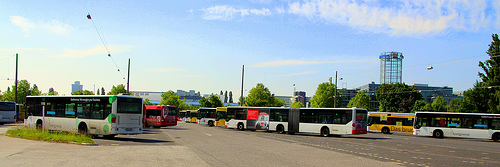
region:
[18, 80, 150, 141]
bus on a road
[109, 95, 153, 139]
the back of a bus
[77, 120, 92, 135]
wheels of a bus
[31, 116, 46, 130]
wheels of a bus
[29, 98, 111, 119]
windows of a bus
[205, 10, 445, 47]
sky full of clouds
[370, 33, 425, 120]
a very tall building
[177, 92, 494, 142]
many buses parked on road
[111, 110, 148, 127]
tail lights of a bus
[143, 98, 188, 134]
a red bus parked on street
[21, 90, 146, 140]
white bus with green marking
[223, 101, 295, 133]
white bus with red panel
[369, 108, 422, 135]
commercial bus mostly yellow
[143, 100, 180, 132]
back end of red bus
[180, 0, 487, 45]
blue sky with high wispy clouds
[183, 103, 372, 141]
row of parked charter busses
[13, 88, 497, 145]
parking lot with mny charter busses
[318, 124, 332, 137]
wheel of white bus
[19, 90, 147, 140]
white bus with green and blue markings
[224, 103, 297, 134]
white bus with red advertising panel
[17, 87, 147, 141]
bus parked on the street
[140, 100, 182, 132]
bus parked on the street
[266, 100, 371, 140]
bus parked on the street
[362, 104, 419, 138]
bus parked on the street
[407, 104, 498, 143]
bus parked on the street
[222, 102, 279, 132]
bus parked on the street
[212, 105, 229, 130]
bus parked on the street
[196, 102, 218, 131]
bus parked on the street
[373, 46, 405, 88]
tower above the street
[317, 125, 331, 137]
tire on a bus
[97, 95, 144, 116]
the back windows of a bus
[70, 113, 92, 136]
wheel of a bus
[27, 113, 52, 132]
front wheel of a bus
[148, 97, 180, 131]
a red bus parked down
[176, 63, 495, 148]
bunch of bus parked down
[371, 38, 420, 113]
a tall building and trees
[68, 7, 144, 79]
a balloon in the sky